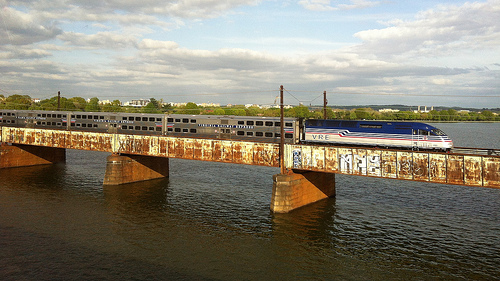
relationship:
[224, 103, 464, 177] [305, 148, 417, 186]
train on bridge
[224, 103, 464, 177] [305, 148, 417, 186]
train over bridge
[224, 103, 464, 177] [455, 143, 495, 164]
train on track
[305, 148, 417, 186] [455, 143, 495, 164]
bridge with track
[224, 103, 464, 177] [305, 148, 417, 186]
train with bridge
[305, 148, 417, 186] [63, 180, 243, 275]
bridge over river